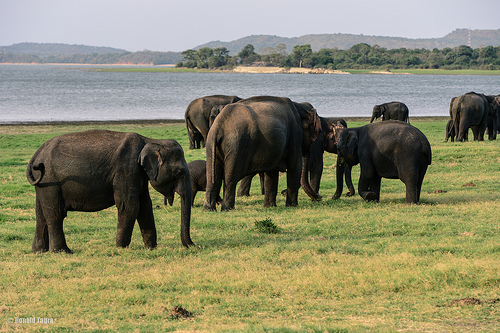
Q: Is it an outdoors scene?
A: Yes, it is outdoors.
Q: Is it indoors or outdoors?
A: It is outdoors.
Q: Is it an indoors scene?
A: No, it is outdoors.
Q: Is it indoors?
A: No, it is outdoors.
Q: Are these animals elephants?
A: Yes, all the animals are elephants.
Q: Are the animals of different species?
A: No, all the animals are elephants.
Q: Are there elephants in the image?
A: Yes, there is an elephant.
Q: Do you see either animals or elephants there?
A: Yes, there is an elephant.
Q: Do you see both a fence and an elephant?
A: No, there is an elephant but no fences.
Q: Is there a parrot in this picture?
A: No, there are no parrots.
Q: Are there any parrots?
A: No, there are no parrots.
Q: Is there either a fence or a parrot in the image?
A: No, there are no parrots or fences.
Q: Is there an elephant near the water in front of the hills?
A: Yes, there is an elephant near the water.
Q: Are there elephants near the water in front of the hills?
A: Yes, there is an elephant near the water.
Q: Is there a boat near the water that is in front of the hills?
A: No, there is an elephant near the water.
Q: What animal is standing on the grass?
A: The elephant is standing on the grass.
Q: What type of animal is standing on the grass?
A: The animal is an elephant.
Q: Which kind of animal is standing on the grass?
A: The animal is an elephant.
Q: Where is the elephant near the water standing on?
A: The elephant is standing on the grass.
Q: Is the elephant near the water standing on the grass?
A: Yes, the elephant is standing on the grass.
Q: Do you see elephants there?
A: Yes, there is an elephant.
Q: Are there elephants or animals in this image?
A: Yes, there is an elephant.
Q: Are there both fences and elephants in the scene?
A: No, there is an elephant but no fences.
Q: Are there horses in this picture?
A: No, there are no horses.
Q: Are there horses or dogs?
A: No, there are no horses or dogs.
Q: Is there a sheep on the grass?
A: No, there is an elephant on the grass.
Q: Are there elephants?
A: Yes, there is an elephant.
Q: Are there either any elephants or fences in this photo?
A: Yes, there is an elephant.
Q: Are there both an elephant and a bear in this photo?
A: No, there is an elephant but no bears.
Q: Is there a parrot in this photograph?
A: No, there are no parrots.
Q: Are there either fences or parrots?
A: No, there are no parrots or fences.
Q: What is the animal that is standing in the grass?
A: The animal is an elephant.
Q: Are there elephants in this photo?
A: Yes, there is an elephant.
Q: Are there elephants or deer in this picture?
A: Yes, there is an elephant.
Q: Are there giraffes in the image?
A: No, there are no giraffes.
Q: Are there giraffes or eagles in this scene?
A: No, there are no giraffes or eagles.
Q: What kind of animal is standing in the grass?
A: The animal is an elephant.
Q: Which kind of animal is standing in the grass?
A: The animal is an elephant.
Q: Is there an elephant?
A: Yes, there is an elephant.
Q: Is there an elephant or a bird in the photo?
A: Yes, there is an elephant.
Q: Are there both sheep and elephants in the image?
A: No, there is an elephant but no sheep.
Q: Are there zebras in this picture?
A: No, there are no zebras.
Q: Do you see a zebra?
A: No, there are no zebras.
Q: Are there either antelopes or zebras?
A: No, there are no zebras or antelopes.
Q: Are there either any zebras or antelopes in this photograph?
A: No, there are no zebras or antelopes.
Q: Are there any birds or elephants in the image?
A: Yes, there is an elephant.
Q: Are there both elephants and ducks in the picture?
A: No, there is an elephant but no ducks.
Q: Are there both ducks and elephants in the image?
A: No, there is an elephant but no ducks.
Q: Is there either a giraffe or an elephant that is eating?
A: Yes, the elephant is eating.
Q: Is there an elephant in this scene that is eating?
A: Yes, there is an elephant that is eating.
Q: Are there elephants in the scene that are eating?
A: Yes, there is an elephant that is eating.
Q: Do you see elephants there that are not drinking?
A: Yes, there is an elephant that is eating .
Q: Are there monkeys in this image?
A: No, there are no monkeys.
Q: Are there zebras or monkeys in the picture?
A: No, there are no monkeys or zebras.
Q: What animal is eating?
A: The animal is an elephant.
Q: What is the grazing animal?
A: The animal is an elephant.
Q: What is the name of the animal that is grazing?
A: The animal is an elephant.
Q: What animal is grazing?
A: The animal is an elephant.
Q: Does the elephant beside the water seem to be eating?
A: Yes, the elephant is eating.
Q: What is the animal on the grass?
A: The animal is an elephant.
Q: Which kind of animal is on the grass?
A: The animal is an elephant.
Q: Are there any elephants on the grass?
A: Yes, there is an elephant on the grass.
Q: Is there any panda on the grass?
A: No, there is an elephant on the grass.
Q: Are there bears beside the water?
A: No, there is an elephant beside the water.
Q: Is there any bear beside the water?
A: No, there is an elephant beside the water.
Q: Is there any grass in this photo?
A: Yes, there is grass.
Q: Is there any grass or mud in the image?
A: Yes, there is grass.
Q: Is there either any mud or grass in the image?
A: Yes, there is grass.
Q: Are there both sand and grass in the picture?
A: Yes, there are both grass and sand.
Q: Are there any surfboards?
A: No, there are no surfboards.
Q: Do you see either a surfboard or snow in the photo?
A: No, there are no surfboards or snow.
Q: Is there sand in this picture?
A: Yes, there is sand.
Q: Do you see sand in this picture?
A: Yes, there is sand.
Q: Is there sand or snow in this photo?
A: Yes, there is sand.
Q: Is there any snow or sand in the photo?
A: Yes, there is sand.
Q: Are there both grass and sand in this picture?
A: Yes, there are both sand and grass.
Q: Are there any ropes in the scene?
A: No, there are no ropes.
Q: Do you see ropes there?
A: No, there are no ropes.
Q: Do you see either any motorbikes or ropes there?
A: No, there are no ropes or motorbikes.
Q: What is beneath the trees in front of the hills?
A: The sand is beneath the trees.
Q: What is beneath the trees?
A: The sand is beneath the trees.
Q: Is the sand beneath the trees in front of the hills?
A: Yes, the sand is beneath the trees.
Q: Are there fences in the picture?
A: No, there are no fences.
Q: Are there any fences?
A: No, there are no fences.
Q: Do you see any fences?
A: No, there are no fences.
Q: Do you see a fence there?
A: No, there are no fences.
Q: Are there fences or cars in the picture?
A: No, there are no fences or cars.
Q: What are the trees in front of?
A: The trees are in front of the hills.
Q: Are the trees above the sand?
A: Yes, the trees are above the sand.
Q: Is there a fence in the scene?
A: No, there are no fences.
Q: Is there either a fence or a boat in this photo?
A: No, there are no fences or boats.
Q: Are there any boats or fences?
A: No, there are no fences or boats.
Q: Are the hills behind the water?
A: Yes, the hills are behind the water.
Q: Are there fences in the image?
A: No, there are no fences.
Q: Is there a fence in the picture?
A: No, there are no fences.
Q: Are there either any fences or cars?
A: No, there are no fences or cars.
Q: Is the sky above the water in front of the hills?
A: Yes, the sky is above the water.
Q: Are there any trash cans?
A: No, there are no trash cans.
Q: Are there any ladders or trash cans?
A: No, there are no trash cans or ladders.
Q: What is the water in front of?
A: The water is in front of the hills.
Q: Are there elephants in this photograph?
A: Yes, there is an elephant.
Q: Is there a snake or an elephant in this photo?
A: Yes, there is an elephant.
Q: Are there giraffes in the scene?
A: No, there are no giraffes.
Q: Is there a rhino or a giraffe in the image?
A: No, there are no giraffes or rhinos.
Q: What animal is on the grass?
A: The animal is an elephant.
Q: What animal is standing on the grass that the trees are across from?
A: The elephant is standing on the grass.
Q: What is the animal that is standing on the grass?
A: The animal is an elephant.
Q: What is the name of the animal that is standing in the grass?
A: The animal is an elephant.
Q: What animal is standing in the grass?
A: The animal is an elephant.